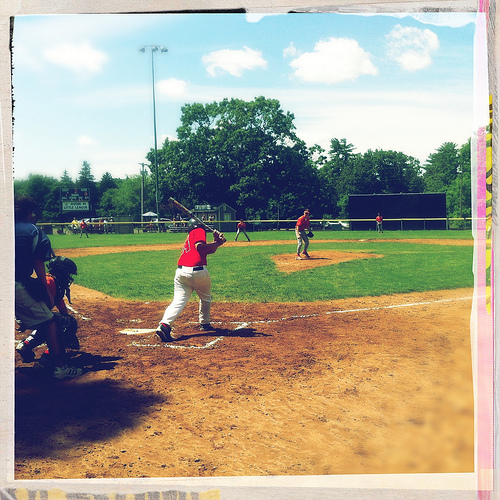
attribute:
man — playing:
[155, 216, 228, 342]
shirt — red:
[176, 227, 207, 267]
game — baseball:
[14, 196, 471, 381]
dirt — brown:
[14, 239, 475, 480]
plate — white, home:
[118, 328, 156, 336]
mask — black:
[47, 256, 78, 290]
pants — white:
[159, 265, 212, 326]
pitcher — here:
[294, 209, 315, 261]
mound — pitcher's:
[269, 250, 385, 274]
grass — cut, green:
[44, 229, 491, 304]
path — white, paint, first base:
[65, 295, 473, 350]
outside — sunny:
[12, 12, 476, 479]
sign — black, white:
[59, 187, 93, 235]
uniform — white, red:
[159, 227, 212, 329]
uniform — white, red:
[23, 255, 78, 355]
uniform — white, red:
[294, 215, 310, 254]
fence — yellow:
[35, 217, 471, 235]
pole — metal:
[137, 44, 168, 233]